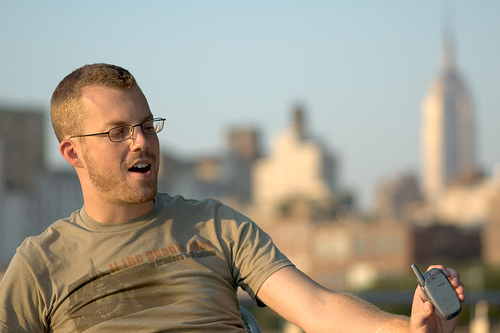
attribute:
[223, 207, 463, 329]
arm — extended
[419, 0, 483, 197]
building — empire state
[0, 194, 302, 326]
t-shirt — tan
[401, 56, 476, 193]
skycraper — tall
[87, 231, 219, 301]
shirt — tan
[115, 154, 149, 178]
mouth — open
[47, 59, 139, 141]
hair — short, blond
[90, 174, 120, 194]
hair — blond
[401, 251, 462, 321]
phone — grey, flip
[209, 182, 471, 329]
arm — extended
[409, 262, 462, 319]
phone — gray, small, grey, cell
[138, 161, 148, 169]
teeth — white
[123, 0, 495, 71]
sky — blue, daytime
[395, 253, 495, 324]
phone — flip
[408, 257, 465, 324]
phone — silver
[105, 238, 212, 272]
words — orange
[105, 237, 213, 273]
letters — red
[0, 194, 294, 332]
shirt — brown